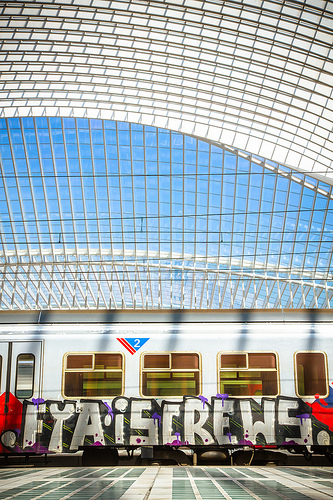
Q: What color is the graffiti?
A: White.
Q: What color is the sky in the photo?
A: Blue.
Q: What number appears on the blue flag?
A: Two.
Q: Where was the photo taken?
A: A train station.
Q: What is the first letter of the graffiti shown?
A: F.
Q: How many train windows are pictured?
A: Five.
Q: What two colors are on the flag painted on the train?
A: Red and blue.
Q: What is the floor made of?
A: Tiles.